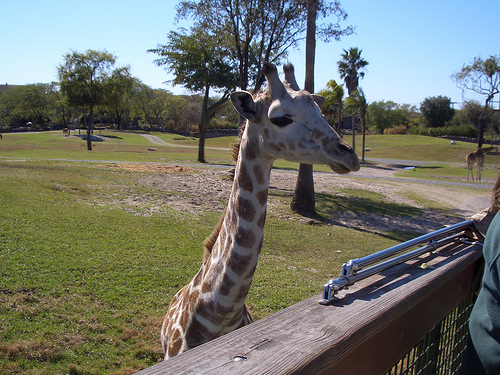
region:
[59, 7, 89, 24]
this is the sky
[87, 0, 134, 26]
the sky is blue in color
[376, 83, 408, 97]
the sky has clouds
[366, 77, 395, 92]
the clouds are white in color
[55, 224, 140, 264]
this is the grass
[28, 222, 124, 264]
the grass is green in color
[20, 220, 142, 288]
the grass is short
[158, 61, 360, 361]
this is a giraffe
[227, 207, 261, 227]
the fur is brown in color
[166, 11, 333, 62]
these are some trees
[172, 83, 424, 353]
This is an animal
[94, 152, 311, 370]
The animal is a giraffe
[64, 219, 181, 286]
This is a park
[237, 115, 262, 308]
This is a long neck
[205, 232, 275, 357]
The necks are spotted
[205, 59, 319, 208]
This is an ear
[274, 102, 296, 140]
This is an eye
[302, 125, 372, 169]
This is a nose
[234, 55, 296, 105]
This is a horn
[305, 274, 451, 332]
This is a bar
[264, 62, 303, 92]
Horns on top of giraffe head.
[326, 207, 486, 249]
A hand railing n the fence.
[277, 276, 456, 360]
Top of fence is wooden.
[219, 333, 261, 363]
A nail in the wood.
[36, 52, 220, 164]
Trees in the zoo pen.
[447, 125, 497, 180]
A giraffe in the distance.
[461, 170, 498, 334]
People standing by the fence.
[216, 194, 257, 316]
The giraffe has brown spots.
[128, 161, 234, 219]
Dirt on the grass.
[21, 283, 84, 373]
Brown patches in the grass.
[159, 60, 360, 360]
giraffe is in front of a fence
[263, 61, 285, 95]
horn next to horn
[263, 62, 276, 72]
the tip of the horn is black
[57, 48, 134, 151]
tree behind giraffe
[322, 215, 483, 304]
metal bar on top of wooden fence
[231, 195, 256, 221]
brown spot on the giraffe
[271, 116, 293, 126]
dark eye under horn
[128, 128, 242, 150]
paved path behind giraffe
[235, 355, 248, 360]
metal bolt on fence railing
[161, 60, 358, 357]
giraffe is standing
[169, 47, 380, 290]
the girrafe is brown in colour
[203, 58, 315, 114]
it has horns on the head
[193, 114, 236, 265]
it has hair on its back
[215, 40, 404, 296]
it has stretched its head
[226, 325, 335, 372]
the fence is brown in colour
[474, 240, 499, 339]
the jumper is green in colour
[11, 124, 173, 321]
the grass is scarcely planted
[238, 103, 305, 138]
the eyes are black in colour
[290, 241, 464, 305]
the metal is silver in colour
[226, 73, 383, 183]
the skin has patterns